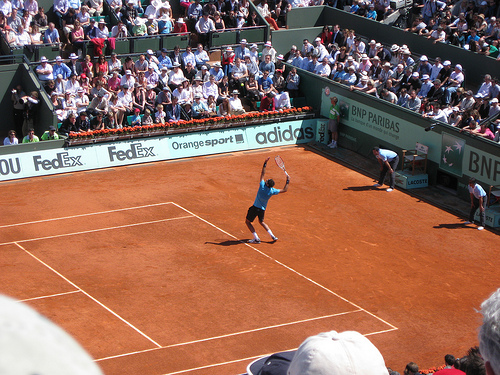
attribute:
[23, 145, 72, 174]
letter — black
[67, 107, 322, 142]
flowers — red, display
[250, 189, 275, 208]
shirt — light blue 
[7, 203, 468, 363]
tennis court — Brown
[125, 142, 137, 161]
letter — black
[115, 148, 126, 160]
black letter — black 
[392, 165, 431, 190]
box — wooden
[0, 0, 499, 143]
people — Watching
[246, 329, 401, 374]
hat — White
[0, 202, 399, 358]
lines — white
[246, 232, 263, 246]
sock — white 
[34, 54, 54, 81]
spectators — watching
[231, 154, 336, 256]
player — Swinging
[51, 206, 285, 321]
court — Brown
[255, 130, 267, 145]
letter — black 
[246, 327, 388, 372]
spectator's cap — white 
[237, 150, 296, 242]
man — standing, serving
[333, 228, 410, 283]
court — Brown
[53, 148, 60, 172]
letter — black 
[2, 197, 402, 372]
tennis court — clay 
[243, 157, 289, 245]
tennis player — male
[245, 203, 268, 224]
shorts — dark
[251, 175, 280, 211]
shirt — blue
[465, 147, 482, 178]
letter — black